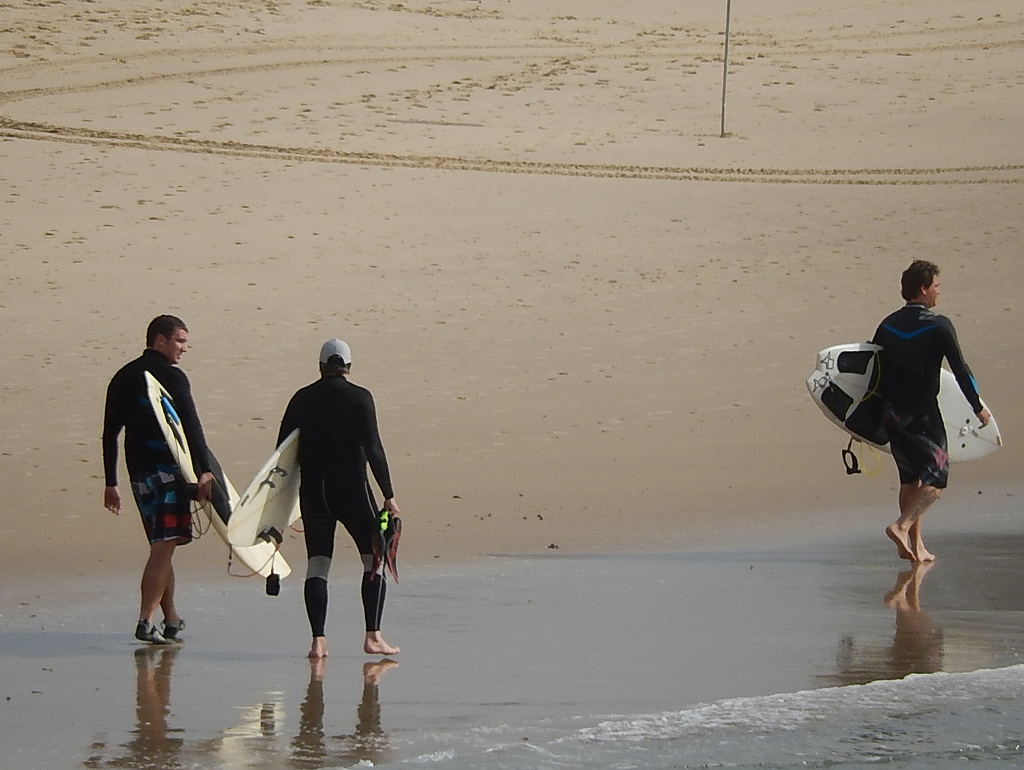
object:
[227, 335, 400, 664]
human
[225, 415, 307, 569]
surfboard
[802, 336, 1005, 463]
surfboard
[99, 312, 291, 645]
human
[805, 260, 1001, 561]
human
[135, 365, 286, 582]
surfboard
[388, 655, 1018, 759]
wave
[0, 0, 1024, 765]
shore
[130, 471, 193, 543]
shorts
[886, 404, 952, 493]
shorts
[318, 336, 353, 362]
hat